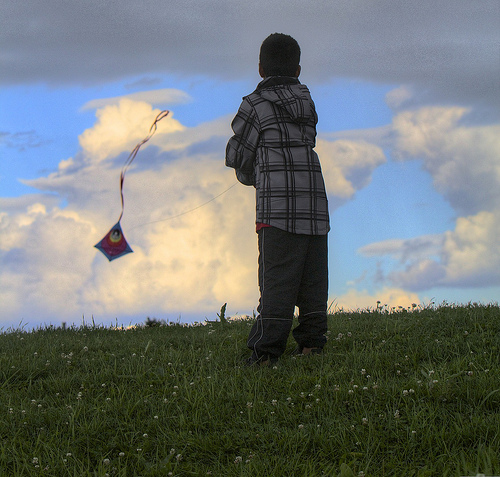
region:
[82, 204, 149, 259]
kite in the sky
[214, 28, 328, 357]
a young boy is standing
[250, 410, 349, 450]
tall green grass here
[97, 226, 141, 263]
rainbow pattern on kite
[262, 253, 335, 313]
jeans on the boy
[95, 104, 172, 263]
a red and blue kite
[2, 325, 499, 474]
a long field of grass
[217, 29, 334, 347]
a boy in a striped jacket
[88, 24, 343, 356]
a boy flying a red kite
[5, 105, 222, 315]
a cloudy blue sky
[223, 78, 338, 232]
a striped blue and white jacket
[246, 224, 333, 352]
a pair of grey pants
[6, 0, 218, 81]
dark gray clouds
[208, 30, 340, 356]
a young boy in a field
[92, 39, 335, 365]
a young boy flying a kite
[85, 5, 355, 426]
the little boy is flying a kite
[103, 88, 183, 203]
the kite has a red tail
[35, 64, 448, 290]
the sky is mostly cloudy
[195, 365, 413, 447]
flowers in the grass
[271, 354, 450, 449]
the flowers are white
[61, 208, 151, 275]
the kite is blue and red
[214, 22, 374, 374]
the boy is standing on the grass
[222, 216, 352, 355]
the pants are black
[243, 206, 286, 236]
the shirt is red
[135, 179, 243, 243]
the string is long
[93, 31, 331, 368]
A little boy flying a kite.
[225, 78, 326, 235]
The boy is wearing a plaid jacket.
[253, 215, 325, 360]
Dark pants with a white stripe on the leg.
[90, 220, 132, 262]
A red blue and yellow kite.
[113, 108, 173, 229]
A long red kite tail.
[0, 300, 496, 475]
Green grass on the gound.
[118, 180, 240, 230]
A white kite string.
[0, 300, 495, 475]
Small white flowers growing in the grass.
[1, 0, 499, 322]
Billowing clouds in the sky.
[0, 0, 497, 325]
Blue sky behind the clouds.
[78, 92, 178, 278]
a kite is flying in the sky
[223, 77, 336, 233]
the boy has a plaid hoodie on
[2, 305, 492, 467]
green grass and weeds are in the field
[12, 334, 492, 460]
white flowers are in the field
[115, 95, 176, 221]
the kite has two tails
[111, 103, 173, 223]
the tails of the kite are red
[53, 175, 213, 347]
the kite is heading down to earth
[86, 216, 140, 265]
the kite is red with a blue trimm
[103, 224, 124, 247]
a round yellow spot is on the kite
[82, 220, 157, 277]
multi colored kite in sky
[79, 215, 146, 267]
multi colored kite in sky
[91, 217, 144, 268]
multi colored kite in sky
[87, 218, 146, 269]
multi colored kite in sky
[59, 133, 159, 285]
A kite flying in the sky.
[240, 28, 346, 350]
A little boy is flying the kite.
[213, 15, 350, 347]
The little boy is standing in the grass.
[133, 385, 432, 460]
White flowers in the grass.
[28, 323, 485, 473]
The grass is green.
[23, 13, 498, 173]
The sky is blue and full of clouds.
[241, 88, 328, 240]
The boy is wearing a hoodie.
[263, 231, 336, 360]
The jeans are black.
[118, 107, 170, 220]
The strings of the kite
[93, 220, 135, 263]
The kite in the air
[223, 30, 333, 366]
The boy on the hillside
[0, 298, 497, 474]
The grassy hillside